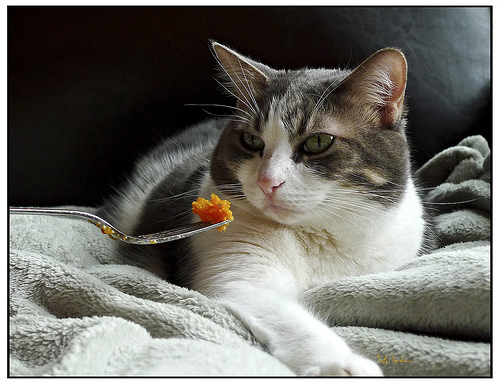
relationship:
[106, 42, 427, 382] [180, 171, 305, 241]
cat being fed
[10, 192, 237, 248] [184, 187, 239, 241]
fork with orange food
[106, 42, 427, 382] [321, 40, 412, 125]
cat has ear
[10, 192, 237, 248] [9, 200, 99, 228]
fork has handle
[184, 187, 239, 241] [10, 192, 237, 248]
food on fork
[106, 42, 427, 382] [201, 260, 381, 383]
cat seen arm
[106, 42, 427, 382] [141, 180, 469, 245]
cat has whiskers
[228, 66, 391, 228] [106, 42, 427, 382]
face of a cat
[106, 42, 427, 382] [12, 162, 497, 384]
cat under blanket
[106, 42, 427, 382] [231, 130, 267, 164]
cat has eye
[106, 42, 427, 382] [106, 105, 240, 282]
cat has body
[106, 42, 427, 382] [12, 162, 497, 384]
cat on blanket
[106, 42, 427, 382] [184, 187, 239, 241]
car fed food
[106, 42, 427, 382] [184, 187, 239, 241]
cat looking at food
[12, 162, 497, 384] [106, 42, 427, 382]
blanket under cat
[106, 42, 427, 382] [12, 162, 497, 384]
cat laying on blanket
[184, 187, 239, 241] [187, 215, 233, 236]
food on tip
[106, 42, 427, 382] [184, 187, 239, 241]
cat starring at food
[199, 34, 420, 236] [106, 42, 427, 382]
face on cat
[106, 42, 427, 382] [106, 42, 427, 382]
sun reflecting on cat